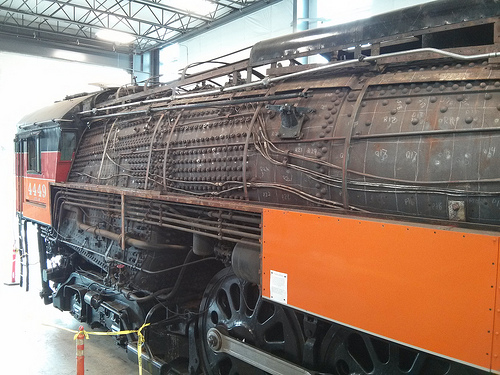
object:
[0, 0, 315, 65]
scaffolding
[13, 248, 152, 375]
tape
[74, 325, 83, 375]
cone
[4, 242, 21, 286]
cone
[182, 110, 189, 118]
rivet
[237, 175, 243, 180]
rivet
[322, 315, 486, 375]
wheel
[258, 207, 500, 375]
panel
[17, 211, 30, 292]
stair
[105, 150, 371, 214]
wire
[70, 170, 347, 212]
wire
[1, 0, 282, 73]
roof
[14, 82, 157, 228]
front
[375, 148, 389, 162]
measurement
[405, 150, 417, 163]
measurement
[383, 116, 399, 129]
measurement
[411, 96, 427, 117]
measurement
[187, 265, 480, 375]
train wheels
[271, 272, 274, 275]
screw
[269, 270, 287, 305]
white sign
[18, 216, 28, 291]
ladder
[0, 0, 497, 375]
train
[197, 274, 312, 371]
wheel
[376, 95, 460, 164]
chalk writing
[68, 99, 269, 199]
steel rivets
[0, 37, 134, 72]
silver door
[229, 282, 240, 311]
groove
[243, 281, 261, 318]
groove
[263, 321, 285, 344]
groove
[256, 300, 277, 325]
groove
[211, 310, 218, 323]
groove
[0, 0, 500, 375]
locomotive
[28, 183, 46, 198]
number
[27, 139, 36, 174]
window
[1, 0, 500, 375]
building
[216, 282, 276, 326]
spokes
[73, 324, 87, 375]
post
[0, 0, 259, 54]
beam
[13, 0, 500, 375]
train depot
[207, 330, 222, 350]
screw